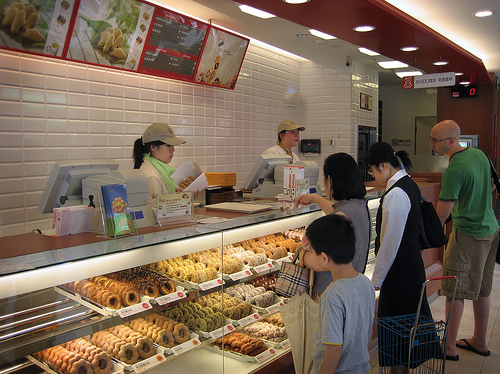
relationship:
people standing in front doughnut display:
[307, 213, 377, 371] [1, 190, 397, 370]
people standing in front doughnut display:
[293, 152, 371, 297] [1, 190, 397, 370]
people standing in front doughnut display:
[366, 143, 441, 371] [1, 190, 397, 370]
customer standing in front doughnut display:
[430, 120, 500, 361] [1, 190, 397, 370]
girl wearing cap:
[133, 123, 200, 209] [138, 122, 188, 144]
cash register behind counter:
[31, 151, 146, 231] [1, 174, 448, 276]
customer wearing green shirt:
[430, 120, 500, 361] [437, 144, 498, 237]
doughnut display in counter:
[1, 211, 380, 374] [0, 172, 454, 372]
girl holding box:
[133, 123, 200, 209] [170, 162, 210, 201]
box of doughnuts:
[170, 162, 210, 201] [167, 175, 195, 189]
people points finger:
[293, 152, 371, 297] [293, 197, 300, 211]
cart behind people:
[382, 273, 457, 372] [359, 142, 440, 372]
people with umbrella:
[293, 152, 371, 297] [277, 270, 327, 372]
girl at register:
[262, 120, 306, 164] [242, 150, 326, 202]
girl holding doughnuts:
[133, 123, 200, 209] [175, 178, 193, 192]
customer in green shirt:
[430, 120, 500, 361] [439, 148, 500, 237]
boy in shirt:
[304, 213, 376, 374] [313, 273, 372, 371]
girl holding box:
[133, 123, 185, 222] [169, 162, 211, 198]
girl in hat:
[258, 114, 309, 169] [275, 120, 309, 132]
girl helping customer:
[258, 114, 309, 169] [421, 115, 498, 367]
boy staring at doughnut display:
[301, 235, 366, 371] [1, 211, 380, 374]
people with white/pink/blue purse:
[293, 152, 371, 297] [269, 246, 311, 295]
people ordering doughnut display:
[293, 152, 371, 297] [1, 211, 380, 374]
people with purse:
[359, 142, 440, 372] [419, 193, 448, 250]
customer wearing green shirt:
[430, 120, 500, 361] [439, 148, 500, 237]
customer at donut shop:
[430, 120, 500, 361] [2, 0, 412, 371]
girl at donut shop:
[133, 123, 200, 209] [2, 0, 412, 371]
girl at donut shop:
[262, 120, 306, 164] [2, 0, 412, 371]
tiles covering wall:
[41, 66, 222, 152] [94, 19, 494, 199]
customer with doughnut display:
[430, 120, 500, 361] [1, 211, 380, 374]